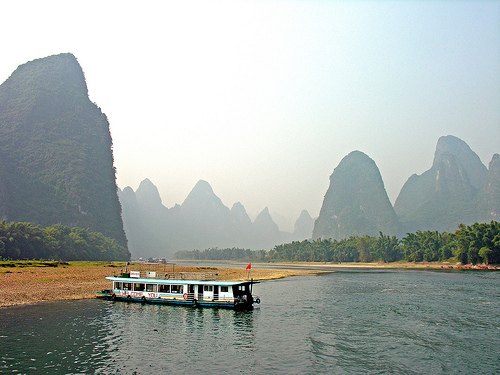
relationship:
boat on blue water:
[97, 260, 258, 316] [3, 261, 493, 370]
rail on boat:
[181, 290, 200, 308] [95, 271, 259, 310]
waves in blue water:
[277, 299, 486, 368] [3, 261, 493, 370]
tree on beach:
[10, 217, 59, 262] [0, 258, 335, 307]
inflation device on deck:
[162, 273, 172, 280] [103, 273, 255, 288]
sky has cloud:
[0, 0, 498, 231] [0, 1, 497, 261]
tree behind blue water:
[439, 226, 485, 270] [3, 261, 493, 370]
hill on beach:
[4, 52, 133, 261] [0, 258, 335, 307]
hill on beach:
[116, 173, 157, 260] [0, 258, 335, 307]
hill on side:
[306, 147, 405, 247] [222, 247, 493, 271]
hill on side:
[389, 132, 489, 225] [222, 247, 493, 271]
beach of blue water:
[0, 258, 335, 307] [3, 261, 493, 370]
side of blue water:
[222, 247, 493, 271] [3, 261, 493, 370]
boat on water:
[97, 260, 258, 316] [134, 315, 326, 366]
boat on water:
[97, 260, 258, 316] [71, 260, 494, 365]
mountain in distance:
[253, 203, 278, 240] [129, 14, 485, 253]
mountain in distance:
[229, 199, 253, 241] [129, 14, 485, 253]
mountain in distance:
[184, 175, 229, 242] [129, 14, 485, 253]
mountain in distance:
[131, 175, 179, 232] [129, 14, 485, 253]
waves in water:
[277, 299, 486, 368] [0, 237, 495, 374]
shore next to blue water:
[1, 255, 498, 305] [3, 261, 493, 370]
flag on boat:
[243, 262, 253, 276] [96, 261, 261, 311]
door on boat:
[197, 284, 219, 298] [102, 273, 261, 314]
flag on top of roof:
[243, 262, 253, 276] [105, 279, 256, 286]